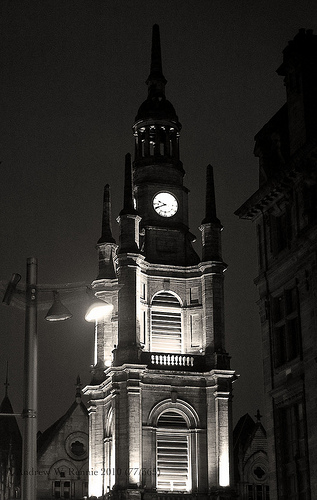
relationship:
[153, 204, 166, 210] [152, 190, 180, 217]
hand on clock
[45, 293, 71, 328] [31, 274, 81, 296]
light hanging from line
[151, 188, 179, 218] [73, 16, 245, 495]
clock on tower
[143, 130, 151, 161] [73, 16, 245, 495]
column on tower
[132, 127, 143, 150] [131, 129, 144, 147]
column on tower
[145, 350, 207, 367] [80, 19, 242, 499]
railing on tower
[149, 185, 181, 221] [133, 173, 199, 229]
light on clock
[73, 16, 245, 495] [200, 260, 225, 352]
tower has column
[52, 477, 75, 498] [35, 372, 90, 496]
window on building